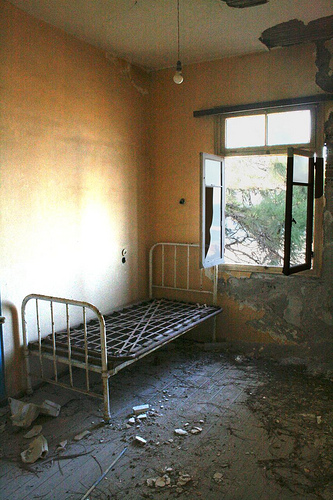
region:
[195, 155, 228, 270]
the window is broken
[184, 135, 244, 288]
the window is broken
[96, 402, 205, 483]
dirt on the floor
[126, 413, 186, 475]
dirt on the floor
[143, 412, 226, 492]
dirt on the floor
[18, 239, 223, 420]
white bed frame with no mattress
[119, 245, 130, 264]
electrical outlet in wall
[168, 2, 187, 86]
light hanging down from ceiling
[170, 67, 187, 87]
white light bulb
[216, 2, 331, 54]
parts of ceiling peeled away due to damage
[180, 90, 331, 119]
black metal curtain rod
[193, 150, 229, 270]
broken window in brown wood frame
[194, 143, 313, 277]
open windows in brown wood frames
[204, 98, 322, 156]
closed white framed sliding window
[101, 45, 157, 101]
cobwebs in corner of room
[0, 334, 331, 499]
The ground beneath the bed frame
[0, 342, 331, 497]
Debris beneath the bed frame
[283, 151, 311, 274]
A broken window door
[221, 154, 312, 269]
The window is open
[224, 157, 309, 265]
A tree out of the window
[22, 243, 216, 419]
A bed frame by the wall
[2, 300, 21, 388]
A shadow on the wall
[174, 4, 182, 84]
A lightbulb near the ceiling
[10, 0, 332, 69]
The roof of the room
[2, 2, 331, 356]
The wall of the room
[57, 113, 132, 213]
yellow surface of the wall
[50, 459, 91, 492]
grey wood surface of the floor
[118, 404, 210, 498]
broken plaster on the floor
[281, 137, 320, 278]
brown wood trim of the window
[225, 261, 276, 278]
white window sill on the wall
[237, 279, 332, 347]
grey broken drywall of the room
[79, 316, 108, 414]
white metal rail of the bed fram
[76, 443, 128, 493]
blue and grey stick on the floor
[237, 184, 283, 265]
tree growing outside the window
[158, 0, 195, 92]
bare bulb and wire hanging from the ceiling